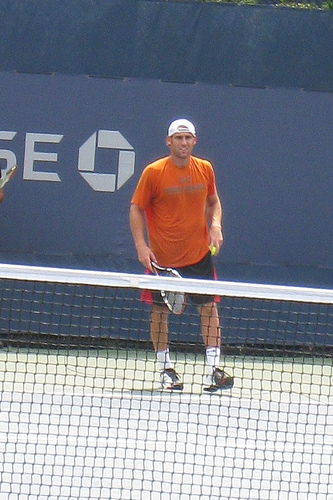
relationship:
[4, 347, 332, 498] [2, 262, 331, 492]
court has net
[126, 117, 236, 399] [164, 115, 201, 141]
man wearing cap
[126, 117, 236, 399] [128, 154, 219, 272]
man wearing t-shirt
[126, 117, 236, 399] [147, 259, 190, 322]
man holding racket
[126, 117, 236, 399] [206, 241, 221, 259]
man holding ball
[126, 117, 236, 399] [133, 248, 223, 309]
man wearing shorts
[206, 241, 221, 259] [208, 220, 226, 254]
ball held in hand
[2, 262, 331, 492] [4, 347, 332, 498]
net on top of court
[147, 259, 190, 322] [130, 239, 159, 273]
racket held in hand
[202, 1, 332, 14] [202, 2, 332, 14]
tree has leaves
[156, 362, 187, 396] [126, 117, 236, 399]
sneaker worn by man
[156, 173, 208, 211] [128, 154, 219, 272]
logo on front of t-shirt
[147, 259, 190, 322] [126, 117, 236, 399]
racket held by man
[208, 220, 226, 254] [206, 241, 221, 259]
hand with ball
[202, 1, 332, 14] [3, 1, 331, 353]
tree on side of tarp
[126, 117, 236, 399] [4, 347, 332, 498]
man on top of court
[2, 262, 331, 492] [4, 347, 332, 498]
net over court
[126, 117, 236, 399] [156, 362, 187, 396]
man wearing sneaker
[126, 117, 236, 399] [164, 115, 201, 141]
man has cap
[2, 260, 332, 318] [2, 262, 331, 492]
strip on top of net